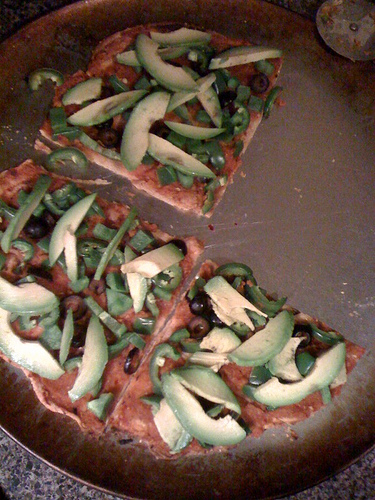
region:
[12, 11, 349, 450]
Three slices of pizza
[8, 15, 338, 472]
Three slices of pizza on a pan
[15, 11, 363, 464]
Three slices of flatbread pizza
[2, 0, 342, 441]
Three slices of pizza with lots of avocado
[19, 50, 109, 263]
Jalapenos topping on a pizza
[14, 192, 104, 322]
Black olives topping on a pizza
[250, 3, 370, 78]
Pizza cutter on a pizza pan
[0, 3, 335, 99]
Burnt edge of pizza pan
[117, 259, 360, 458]
Smallest pizza slice on a pan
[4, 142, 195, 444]
Largest pizza slice of three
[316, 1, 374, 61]
a pizza cutter on the table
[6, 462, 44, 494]
the marble table under the pizza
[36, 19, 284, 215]
a slice of pizza on the platter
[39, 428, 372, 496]
the crust of the pizza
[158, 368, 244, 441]
cut up avacodos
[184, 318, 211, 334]
an olive on the pizza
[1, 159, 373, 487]
half of a pizza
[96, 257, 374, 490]
a slice of pizza with many toppings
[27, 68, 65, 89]
a cut up pepper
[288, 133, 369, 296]
the brown of a pizza platter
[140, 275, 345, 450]
Avocados on a pizza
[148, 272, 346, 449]
Avocados are on a pizza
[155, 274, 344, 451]
Sliced avocados on a pizza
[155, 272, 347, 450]
Sliced avocados are on a pizza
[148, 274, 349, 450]
Avocados on a slice of pizza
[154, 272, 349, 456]
Avocados are on a slice of pizza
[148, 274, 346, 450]
Sliced avocados on a slice of pizza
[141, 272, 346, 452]
Sliced avocados are on a slice of pizza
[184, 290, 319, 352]
Olives on a slice of pizza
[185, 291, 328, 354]
Black olives on a slice of pizza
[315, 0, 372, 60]
Pizza cutter resting on pizza pan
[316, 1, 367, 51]
Cheese and sauce stuck on pizza cutter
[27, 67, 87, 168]
Green peppers laying on pizza pan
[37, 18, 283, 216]
Slice of pizza with toppings on pizza pan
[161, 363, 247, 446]
Avocado on top of pizza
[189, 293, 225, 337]
Sliced olives on top of pizza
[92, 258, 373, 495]
Pizza slice with sauce on the top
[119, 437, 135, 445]
Black speck on side of pizza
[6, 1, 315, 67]
Burned edge on pizza pan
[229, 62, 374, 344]
Empty space on pizza pan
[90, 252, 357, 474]
A slice of brown pizza.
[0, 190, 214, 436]
a slice of a avocado covered pizza.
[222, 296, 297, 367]
a slice of green avocado.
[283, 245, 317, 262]
a section of a pizza pan.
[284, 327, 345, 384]
a green leaf on a slice of pizza.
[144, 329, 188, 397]
a slice of bell pepper.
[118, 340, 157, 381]
a slice of a black olive.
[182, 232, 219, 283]
the center of a pizza.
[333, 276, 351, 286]
a crumb on a pan.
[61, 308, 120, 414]
a slice of green veggie.